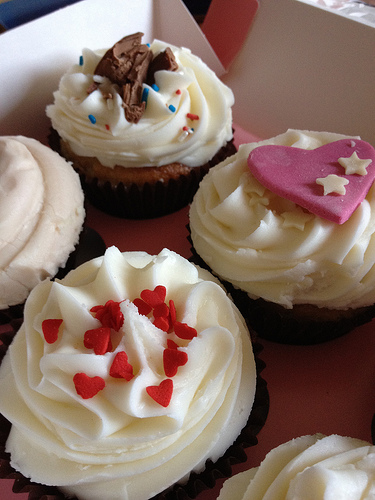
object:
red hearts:
[40, 286, 196, 407]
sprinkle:
[145, 378, 173, 409]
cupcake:
[0, 245, 264, 499]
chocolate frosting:
[94, 31, 177, 127]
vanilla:
[45, 26, 233, 181]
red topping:
[140, 282, 168, 308]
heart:
[245, 133, 374, 227]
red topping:
[186, 110, 200, 122]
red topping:
[174, 87, 183, 94]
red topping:
[103, 121, 111, 129]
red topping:
[144, 377, 175, 408]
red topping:
[83, 327, 113, 353]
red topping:
[141, 272, 165, 411]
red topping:
[33, 296, 164, 398]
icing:
[187, 207, 370, 286]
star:
[336, 152, 371, 177]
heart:
[162, 346, 187, 376]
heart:
[73, 371, 106, 399]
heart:
[109, 350, 134, 381]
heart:
[40, 318, 63, 342]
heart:
[139, 285, 167, 306]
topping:
[84, 326, 110, 352]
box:
[0, 0, 374, 163]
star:
[314, 171, 352, 196]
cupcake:
[45, 27, 239, 223]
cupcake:
[216, 430, 373, 498]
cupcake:
[186, 126, 374, 350]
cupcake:
[0, 135, 93, 328]